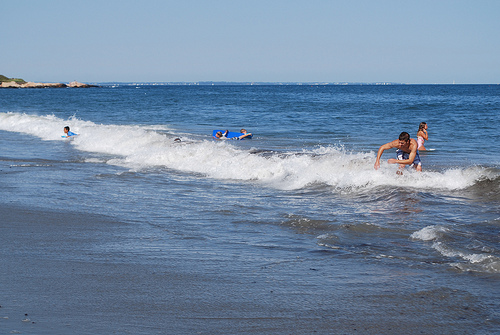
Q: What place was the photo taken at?
A: It was taken at the beach.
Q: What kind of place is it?
A: It is a beach.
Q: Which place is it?
A: It is a beach.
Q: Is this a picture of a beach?
A: Yes, it is showing a beach.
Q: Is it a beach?
A: Yes, it is a beach.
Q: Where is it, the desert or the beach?
A: It is the beach.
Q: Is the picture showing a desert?
A: No, the picture is showing a beach.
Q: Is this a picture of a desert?
A: No, the picture is showing a beach.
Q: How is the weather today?
A: It is clear.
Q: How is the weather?
A: It is clear.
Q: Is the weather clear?
A: Yes, it is clear.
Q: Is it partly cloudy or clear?
A: It is clear.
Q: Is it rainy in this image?
A: No, it is clear.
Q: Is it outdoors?
A: Yes, it is outdoors.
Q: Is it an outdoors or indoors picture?
A: It is outdoors.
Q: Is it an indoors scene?
A: No, it is outdoors.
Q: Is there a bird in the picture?
A: No, there are no birds.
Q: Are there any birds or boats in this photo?
A: No, there are no birds or boats.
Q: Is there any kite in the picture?
A: No, there are no kites.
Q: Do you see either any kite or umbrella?
A: No, there are no kites or umbrellas.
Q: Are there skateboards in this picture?
A: No, there are no skateboards.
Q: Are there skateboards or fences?
A: No, there are no skateboards or fences.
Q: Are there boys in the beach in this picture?
A: Yes, there is a boy in the beach.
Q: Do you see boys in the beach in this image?
A: Yes, there is a boy in the beach.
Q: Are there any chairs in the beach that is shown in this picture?
A: No, there is a boy in the beach.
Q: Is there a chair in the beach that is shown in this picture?
A: No, there is a boy in the beach.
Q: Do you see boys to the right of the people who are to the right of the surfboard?
A: Yes, there is a boy to the right of the people.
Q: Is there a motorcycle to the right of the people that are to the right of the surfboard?
A: No, there is a boy to the right of the people.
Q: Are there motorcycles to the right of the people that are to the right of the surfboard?
A: No, there is a boy to the right of the people.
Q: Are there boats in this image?
A: No, there are no boats.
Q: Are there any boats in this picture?
A: No, there are no boats.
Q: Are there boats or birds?
A: No, there are no boats or birds.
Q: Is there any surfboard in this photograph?
A: Yes, there is a surfboard.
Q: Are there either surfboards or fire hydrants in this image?
A: Yes, there is a surfboard.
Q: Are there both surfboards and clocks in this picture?
A: No, there is a surfboard but no clocks.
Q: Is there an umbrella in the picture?
A: No, there are no umbrellas.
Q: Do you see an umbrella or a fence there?
A: No, there are no umbrellas or fences.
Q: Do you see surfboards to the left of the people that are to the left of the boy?
A: Yes, there is a surfboard to the left of the people.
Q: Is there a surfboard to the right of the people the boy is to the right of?
A: No, the surfboard is to the left of the people.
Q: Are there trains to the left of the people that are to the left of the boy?
A: No, there is a surfboard to the left of the people.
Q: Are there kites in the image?
A: No, there are no kites.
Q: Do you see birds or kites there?
A: No, there are no kites or birds.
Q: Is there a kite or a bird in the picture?
A: No, there are no kites or birds.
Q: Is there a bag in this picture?
A: No, there are no bags.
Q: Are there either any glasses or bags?
A: No, there are no bags or glasses.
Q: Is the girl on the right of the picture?
A: Yes, the girl is on the right of the image.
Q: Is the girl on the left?
A: No, the girl is on the right of the image.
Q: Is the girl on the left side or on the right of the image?
A: The girl is on the right of the image.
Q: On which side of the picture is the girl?
A: The girl is on the right of the image.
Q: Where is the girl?
A: The girl is in the beach.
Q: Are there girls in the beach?
A: Yes, there is a girl in the beach.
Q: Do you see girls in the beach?
A: Yes, there is a girl in the beach.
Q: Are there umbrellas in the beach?
A: No, there is a girl in the beach.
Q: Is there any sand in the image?
A: Yes, there is sand.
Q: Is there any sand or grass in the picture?
A: Yes, there is sand.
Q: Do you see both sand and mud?
A: No, there is sand but no mud.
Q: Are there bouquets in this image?
A: No, there are no bouquets.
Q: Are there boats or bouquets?
A: No, there are no bouquets or boats.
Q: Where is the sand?
A: The sand is on the shore.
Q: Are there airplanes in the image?
A: No, there are no airplanes.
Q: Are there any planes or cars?
A: No, there are no planes or cars.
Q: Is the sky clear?
A: Yes, the sky is clear.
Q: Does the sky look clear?
A: Yes, the sky is clear.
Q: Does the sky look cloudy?
A: No, the sky is clear.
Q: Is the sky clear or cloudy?
A: The sky is clear.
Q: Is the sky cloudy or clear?
A: The sky is clear.